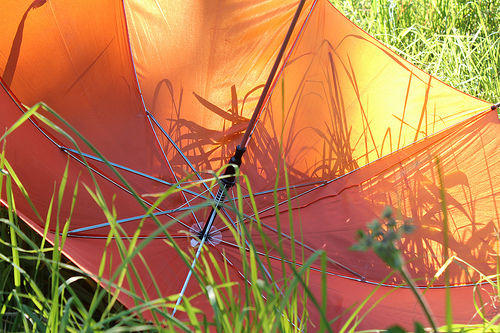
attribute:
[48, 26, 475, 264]
umbrella — orange, open, down, upside, abandoned, red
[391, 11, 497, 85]
grass — green, tall, small, long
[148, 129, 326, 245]
spokes — metal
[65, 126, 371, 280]
wires — metal, silver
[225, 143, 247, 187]
stem — black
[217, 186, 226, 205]
spring — small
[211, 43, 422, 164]
shadow — grass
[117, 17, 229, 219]
frame — metal, silver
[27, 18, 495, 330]
photo — daytime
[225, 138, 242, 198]
object — black